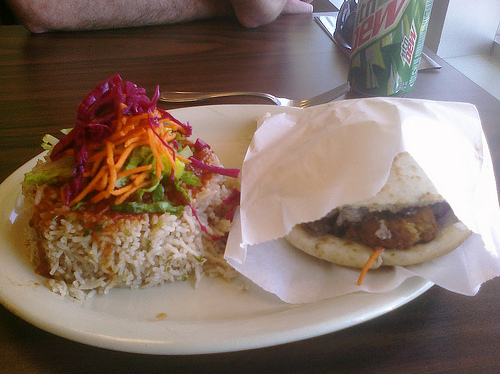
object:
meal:
[47, 206, 220, 281]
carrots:
[92, 152, 116, 184]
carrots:
[148, 117, 167, 178]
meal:
[23, 73, 221, 206]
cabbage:
[188, 158, 243, 177]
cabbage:
[79, 74, 156, 113]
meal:
[23, 74, 474, 297]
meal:
[286, 149, 475, 269]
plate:
[0, 104, 435, 354]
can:
[350, 0, 428, 98]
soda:
[347, 0, 427, 96]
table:
[0, 6, 458, 374]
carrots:
[106, 128, 162, 146]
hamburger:
[284, 155, 475, 273]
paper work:
[246, 96, 496, 284]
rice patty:
[22, 213, 226, 294]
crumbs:
[154, 312, 168, 321]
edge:
[66, 326, 343, 361]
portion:
[180, 311, 263, 346]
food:
[17, 87, 240, 280]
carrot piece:
[356, 246, 382, 285]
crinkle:
[273, 106, 351, 129]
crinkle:
[328, 103, 346, 123]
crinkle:
[369, 98, 443, 119]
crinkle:
[238, 195, 293, 228]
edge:
[273, 265, 471, 306]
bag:
[222, 100, 499, 304]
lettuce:
[134, 163, 198, 209]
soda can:
[347, 0, 431, 100]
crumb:
[150, 312, 166, 322]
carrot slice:
[356, 244, 381, 286]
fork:
[156, 80, 354, 102]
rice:
[43, 227, 194, 281]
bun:
[284, 154, 471, 271]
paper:
[250, 93, 500, 193]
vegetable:
[64, 103, 186, 204]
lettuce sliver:
[112, 202, 185, 215]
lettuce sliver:
[174, 170, 198, 188]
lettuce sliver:
[41, 132, 60, 145]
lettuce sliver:
[20, 170, 63, 184]